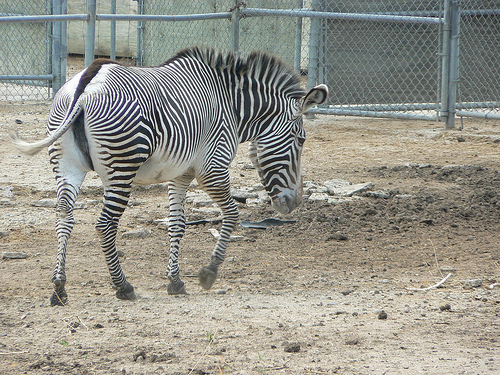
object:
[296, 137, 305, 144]
eye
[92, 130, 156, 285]
hind leg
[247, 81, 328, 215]
head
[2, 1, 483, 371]
pen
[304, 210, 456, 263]
clumps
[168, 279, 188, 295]
hooves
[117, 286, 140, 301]
hooves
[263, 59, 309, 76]
mane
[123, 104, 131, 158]
stripes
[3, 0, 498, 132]
fence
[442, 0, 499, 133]
gate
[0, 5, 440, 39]
pipe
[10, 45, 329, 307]
animal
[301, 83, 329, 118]
ear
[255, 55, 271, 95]
mane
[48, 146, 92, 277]
leg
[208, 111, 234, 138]
stripes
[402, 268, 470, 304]
stick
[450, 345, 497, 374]
dirt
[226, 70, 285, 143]
neck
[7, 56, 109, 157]
rear end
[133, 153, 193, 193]
belly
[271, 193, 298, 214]
mouth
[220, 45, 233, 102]
mane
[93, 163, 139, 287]
leg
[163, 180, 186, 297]
leg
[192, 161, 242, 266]
leg